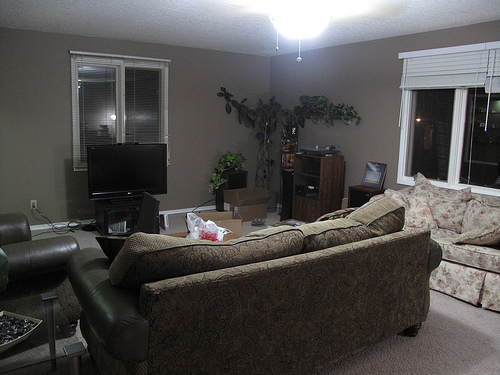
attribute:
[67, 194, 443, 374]
sofa — floral, brown, tan, patterned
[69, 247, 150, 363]
arm — leather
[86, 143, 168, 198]
tv — flat screen, black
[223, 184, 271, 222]
box — cardboard, open, brown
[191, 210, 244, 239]
box — open, cardboard, brown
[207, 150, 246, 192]
plant — green, vine, small, indoor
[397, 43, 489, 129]
blind — white, drawn up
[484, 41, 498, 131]
blind — white, drawn up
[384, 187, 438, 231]
pillow — floral patterned, throw pillow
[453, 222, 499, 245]
pillow — floral patterned, throw pillow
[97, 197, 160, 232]
entertainment center — black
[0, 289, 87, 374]
table — glass, clear, end table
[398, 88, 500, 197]
window — uncovered, white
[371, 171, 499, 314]
sofa — flower patterned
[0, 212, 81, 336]
chair — brown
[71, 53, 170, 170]
window — white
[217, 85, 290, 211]
plant — green, large, indoor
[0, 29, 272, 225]
wall — brown, gray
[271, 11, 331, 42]
light — on, bright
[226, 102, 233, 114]
leaf — green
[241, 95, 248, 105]
leaf — green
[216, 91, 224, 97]
leaf — green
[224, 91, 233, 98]
leaf — green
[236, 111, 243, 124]
leaf — green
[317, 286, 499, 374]
floor — carpeted, light, beige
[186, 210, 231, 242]
bag — white, plastic, red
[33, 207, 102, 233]
cord — black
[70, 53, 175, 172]
frame — white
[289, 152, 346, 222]
stand — brown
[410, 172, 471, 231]
cushion — flowery, tan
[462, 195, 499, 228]
cushion — flowery, tan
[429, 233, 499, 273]
cushion — flowery, tan